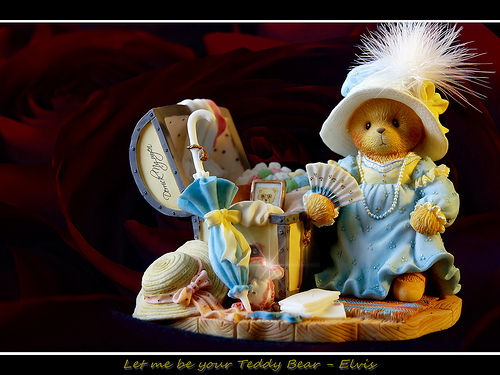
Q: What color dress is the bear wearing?
A: Blue.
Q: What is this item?
A: Figurine.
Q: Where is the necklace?
A: Bears neck.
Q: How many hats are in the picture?
A: 2.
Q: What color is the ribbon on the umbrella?
A: Yellow.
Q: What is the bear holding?
A: Fan.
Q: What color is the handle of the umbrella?
A: White.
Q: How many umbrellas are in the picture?
A: 1.